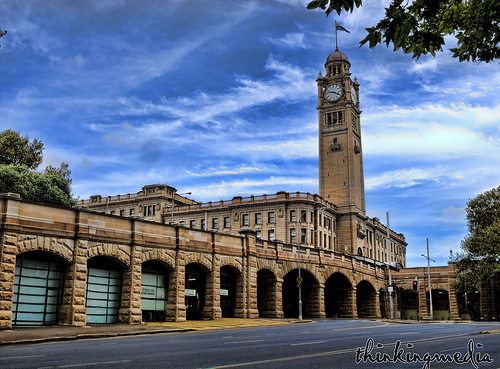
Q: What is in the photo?
A: A building.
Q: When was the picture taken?
A: Daytime.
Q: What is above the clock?
A: A flag.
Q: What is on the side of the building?
A: The street.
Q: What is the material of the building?
A: Stone.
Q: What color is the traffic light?
A: Red.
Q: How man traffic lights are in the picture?
A: One.